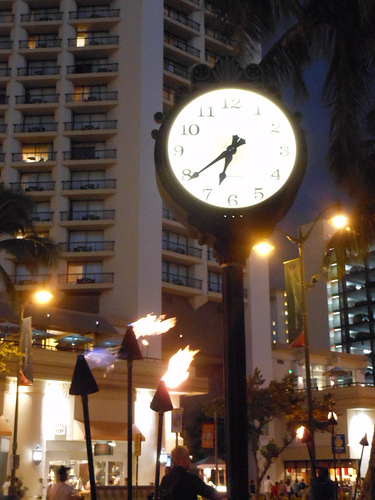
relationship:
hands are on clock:
[186, 132, 246, 189] [149, 59, 311, 238]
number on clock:
[181, 120, 202, 137] [149, 59, 311, 238]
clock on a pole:
[149, 59, 311, 238] [210, 239, 257, 499]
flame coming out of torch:
[128, 313, 177, 338] [116, 326, 147, 500]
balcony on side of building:
[64, 85, 121, 109] [1, 3, 286, 488]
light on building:
[74, 34, 85, 47] [1, 3, 286, 488]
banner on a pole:
[198, 424, 217, 449] [209, 411, 221, 495]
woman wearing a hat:
[44, 462, 88, 499] [49, 464, 74, 472]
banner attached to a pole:
[198, 424, 217, 449] [209, 411, 221, 495]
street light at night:
[318, 196, 363, 355] [8, 18, 365, 482]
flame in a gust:
[128, 313, 177, 338] [124, 314, 180, 350]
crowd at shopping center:
[162, 454, 372, 496] [2, 287, 370, 498]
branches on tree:
[3, 193, 28, 233] [1, 180, 45, 309]